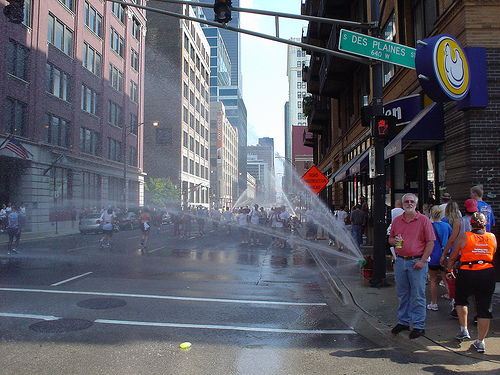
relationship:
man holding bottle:
[385, 194, 437, 343] [393, 232, 404, 251]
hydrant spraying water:
[358, 252, 375, 286] [120, 126, 369, 279]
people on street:
[97, 208, 119, 251] [1, 214, 446, 374]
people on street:
[133, 206, 156, 258] [1, 214, 446, 374]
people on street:
[3, 204, 26, 254] [1, 214, 446, 374]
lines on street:
[2, 284, 329, 309] [1, 214, 446, 374]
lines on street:
[2, 310, 362, 337] [1, 214, 446, 374]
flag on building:
[2, 134, 36, 163] [1, 1, 151, 249]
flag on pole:
[2, 134, 36, 163] [1, 127, 16, 154]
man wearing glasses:
[385, 194, 437, 343] [403, 199, 416, 205]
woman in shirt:
[440, 208, 499, 357] [454, 228, 498, 272]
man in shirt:
[385, 194, 437, 343] [389, 211, 438, 259]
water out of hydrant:
[120, 126, 369, 279] [358, 252, 375, 286]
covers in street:
[27, 315, 94, 338] [1, 214, 446, 374]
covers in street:
[74, 291, 128, 314] [1, 214, 446, 374]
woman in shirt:
[421, 203, 458, 316] [426, 219, 453, 267]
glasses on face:
[403, 199, 416, 205] [402, 195, 419, 214]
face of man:
[402, 195, 419, 214] [385, 194, 437, 343]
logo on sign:
[441, 42, 467, 88] [412, 32, 475, 107]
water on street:
[120, 126, 369, 279] [1, 214, 446, 374]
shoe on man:
[407, 326, 425, 343] [385, 194, 437, 343]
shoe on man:
[390, 321, 412, 336] [385, 194, 437, 343]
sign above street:
[296, 163, 330, 199] [1, 214, 446, 374]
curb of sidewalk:
[303, 235, 352, 305] [306, 233, 500, 372]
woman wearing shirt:
[440, 208, 499, 357] [454, 228, 498, 272]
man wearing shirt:
[385, 194, 437, 343] [389, 211, 438, 259]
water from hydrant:
[120, 126, 369, 279] [358, 252, 375, 286]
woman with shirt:
[421, 203, 458, 316] [426, 219, 453, 267]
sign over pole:
[335, 26, 419, 73] [364, 25, 393, 287]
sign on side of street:
[296, 163, 330, 199] [1, 214, 446, 374]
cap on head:
[463, 196, 478, 214] [461, 199, 481, 219]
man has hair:
[385, 194, 437, 343] [401, 193, 422, 204]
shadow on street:
[327, 344, 500, 370] [1, 214, 446, 374]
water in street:
[120, 126, 369, 279] [1, 214, 446, 374]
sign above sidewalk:
[335, 26, 419, 73] [306, 233, 500, 372]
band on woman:
[455, 257, 496, 269] [440, 208, 499, 357]